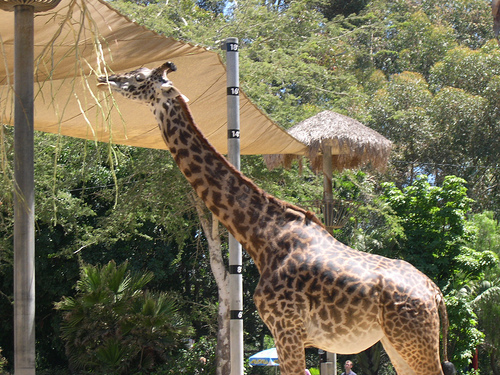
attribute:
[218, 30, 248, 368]
pole — large, metal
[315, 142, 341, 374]
pole — large, wooden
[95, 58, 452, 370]
giraffe — tall, brown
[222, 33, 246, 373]
pole — large, metal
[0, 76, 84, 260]
pole — tall, metal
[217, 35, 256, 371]
pole — marked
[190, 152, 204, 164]
spot — brown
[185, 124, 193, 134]
spot — brown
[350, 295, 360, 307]
spot — brown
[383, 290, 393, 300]
spot — brown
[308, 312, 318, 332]
spot — brown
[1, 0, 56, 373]
pole — metal, large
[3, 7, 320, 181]
canopy — brown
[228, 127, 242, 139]
number — 14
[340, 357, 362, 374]
man — standing in distance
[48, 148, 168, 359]
trees — palm, in background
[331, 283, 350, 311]
spot — brown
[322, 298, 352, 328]
spot — brown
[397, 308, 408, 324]
spot — brown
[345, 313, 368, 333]
spot — brown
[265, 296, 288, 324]
spot — brown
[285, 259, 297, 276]
spot — brown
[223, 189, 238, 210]
spot — brown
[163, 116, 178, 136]
spot — brown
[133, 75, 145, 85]
giraffeeye — giraffe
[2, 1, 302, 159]
sun shade — yellow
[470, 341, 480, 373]
pole — red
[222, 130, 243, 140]
strip — black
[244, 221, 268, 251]
spot — brown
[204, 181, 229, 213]
spot — brown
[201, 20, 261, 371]
pole — metal